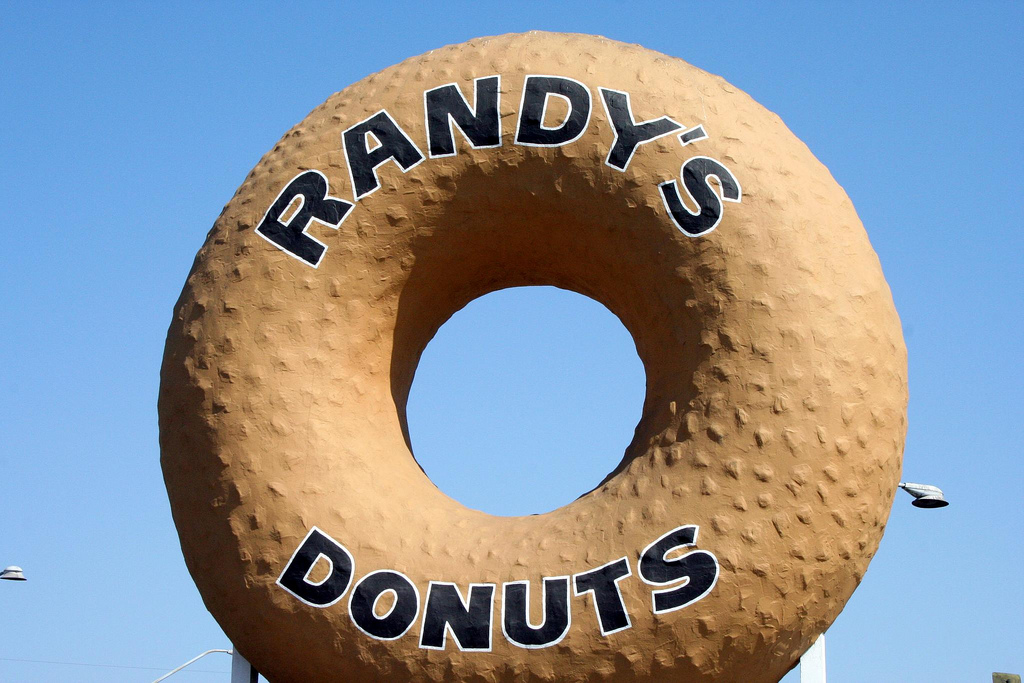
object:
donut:
[156, 25, 905, 683]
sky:
[403, 283, 648, 519]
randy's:
[252, 73, 741, 267]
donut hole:
[397, 280, 652, 516]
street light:
[0, 566, 26, 580]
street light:
[895, 482, 950, 509]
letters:
[255, 73, 740, 660]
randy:
[253, 73, 682, 265]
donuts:
[266, 527, 727, 659]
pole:
[227, 644, 263, 681]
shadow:
[390, 264, 662, 524]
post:
[797, 628, 826, 680]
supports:
[230, 632, 822, 683]